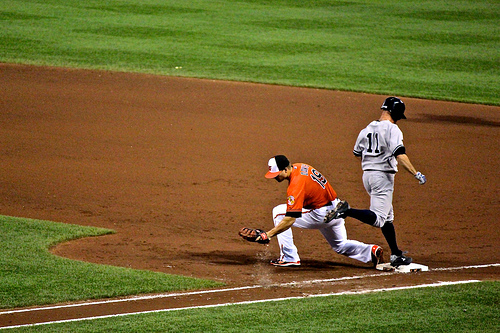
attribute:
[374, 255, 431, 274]
base — white, padded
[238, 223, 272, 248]
glove — great, baseball, brown, black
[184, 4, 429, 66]
grass — green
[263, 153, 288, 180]
hat — lovely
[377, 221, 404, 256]
socks — tall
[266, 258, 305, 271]
shoes — orange, black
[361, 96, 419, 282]
player — running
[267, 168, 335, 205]
jersey — orange, black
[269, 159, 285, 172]
cap — baseball, orange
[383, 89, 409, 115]
helmet — black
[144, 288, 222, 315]
lines — white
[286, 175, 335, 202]
shirt — orange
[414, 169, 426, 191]
gloves — white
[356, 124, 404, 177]
jersey — white, grey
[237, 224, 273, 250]
mitt — leather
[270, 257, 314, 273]
cleat — black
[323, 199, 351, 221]
cleat — white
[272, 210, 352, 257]
pants — orange, white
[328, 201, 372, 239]
cleats — black